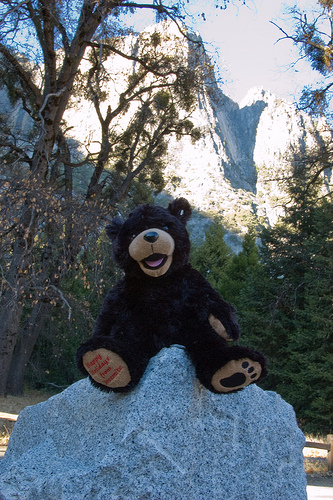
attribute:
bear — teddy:
[81, 197, 294, 429]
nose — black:
[142, 221, 158, 244]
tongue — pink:
[143, 254, 166, 274]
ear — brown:
[162, 189, 207, 233]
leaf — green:
[239, 273, 277, 322]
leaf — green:
[302, 387, 317, 423]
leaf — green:
[275, 369, 297, 392]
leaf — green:
[258, 313, 299, 371]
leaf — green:
[312, 332, 322, 356]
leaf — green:
[289, 356, 307, 382]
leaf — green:
[265, 375, 291, 395]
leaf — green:
[305, 391, 321, 419]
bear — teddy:
[77, 183, 265, 431]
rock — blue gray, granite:
[4, 346, 317, 498]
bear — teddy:
[65, 176, 274, 407]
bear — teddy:
[74, 184, 281, 400]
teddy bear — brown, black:
[72, 195, 271, 397]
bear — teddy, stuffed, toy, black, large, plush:
[70, 194, 271, 401]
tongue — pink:
[140, 255, 170, 270]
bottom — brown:
[79, 347, 134, 388]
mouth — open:
[136, 249, 171, 271]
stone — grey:
[0, 340, 315, 496]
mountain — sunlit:
[0, 23, 331, 231]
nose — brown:
[142, 230, 162, 242]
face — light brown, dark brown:
[111, 206, 200, 279]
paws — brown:
[74, 346, 264, 393]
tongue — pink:
[140, 254, 164, 267]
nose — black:
[144, 228, 161, 241]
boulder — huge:
[1, 336, 309, 497]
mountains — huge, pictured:
[0, 19, 331, 258]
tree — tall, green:
[213, 101, 331, 434]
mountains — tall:
[0, 15, 331, 234]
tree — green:
[216, 210, 269, 366]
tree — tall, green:
[194, 214, 239, 299]